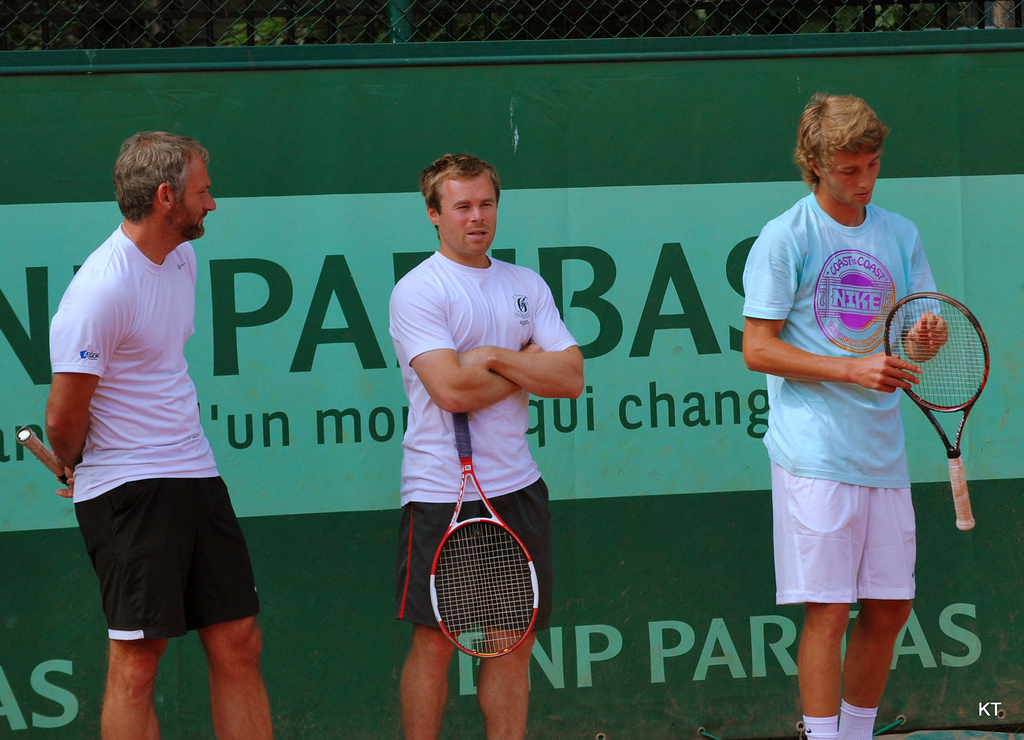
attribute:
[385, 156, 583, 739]
man — looking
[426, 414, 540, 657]
racket — upside down, red, white, black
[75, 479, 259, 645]
shorts — black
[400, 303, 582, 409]
arms — folded, crossed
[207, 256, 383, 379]
letters — big, green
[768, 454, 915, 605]
shorts — white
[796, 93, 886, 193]
hair — blonde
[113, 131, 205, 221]
hair — gray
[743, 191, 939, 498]
shirt — blue, white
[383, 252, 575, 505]
shirt — white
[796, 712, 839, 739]
socks — white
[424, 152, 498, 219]
hair — brown